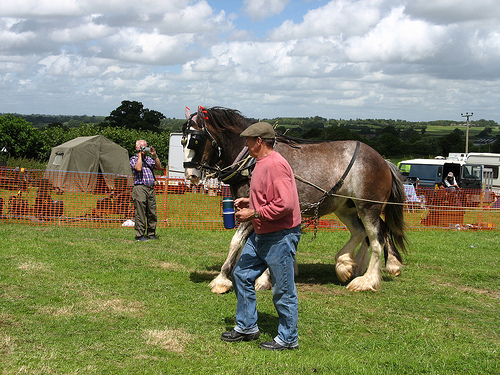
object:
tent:
[40, 134, 135, 197]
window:
[52, 149, 66, 168]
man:
[219, 120, 304, 353]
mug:
[221, 196, 236, 215]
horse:
[179, 102, 410, 294]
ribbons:
[198, 104, 210, 123]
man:
[128, 136, 166, 242]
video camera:
[139, 144, 155, 158]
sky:
[1, 0, 499, 123]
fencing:
[0, 165, 499, 234]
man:
[443, 171, 461, 194]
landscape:
[1, 100, 499, 159]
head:
[445, 171, 456, 181]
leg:
[230, 235, 270, 334]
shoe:
[221, 328, 261, 342]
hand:
[233, 196, 250, 210]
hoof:
[335, 259, 358, 282]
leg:
[345, 202, 388, 294]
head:
[181, 104, 225, 181]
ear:
[195, 104, 208, 129]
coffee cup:
[222, 207, 237, 229]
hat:
[239, 122, 276, 139]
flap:
[98, 155, 119, 192]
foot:
[207, 277, 234, 295]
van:
[396, 156, 485, 202]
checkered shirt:
[129, 153, 156, 189]